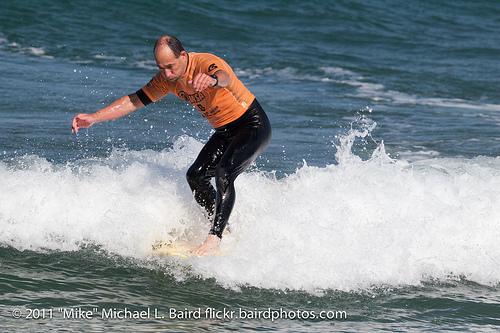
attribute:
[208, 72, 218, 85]
watch — black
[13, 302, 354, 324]
writing — on photo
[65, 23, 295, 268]
man — balding, surfing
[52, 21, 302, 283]
surfer — on board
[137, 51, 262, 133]
shirt — orange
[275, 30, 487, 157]
ocean — is wet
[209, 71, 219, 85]
wrist watch — on man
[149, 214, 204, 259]
surfboard — on man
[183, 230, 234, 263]
feet — are wet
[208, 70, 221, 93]
watch — on photo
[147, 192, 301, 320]
surfer — has brown hair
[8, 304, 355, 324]
writing — white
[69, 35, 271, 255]
man — wearing, balancing, holding, surfing, on board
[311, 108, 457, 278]
wave — small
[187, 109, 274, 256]
wetsuit — black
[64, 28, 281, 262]
man — standing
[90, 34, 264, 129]
shirt — orange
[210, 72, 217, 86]
wristwatch — black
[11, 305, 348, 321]
description — written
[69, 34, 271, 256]
surfer — is wet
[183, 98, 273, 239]
pants — black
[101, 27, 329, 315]
man — barefoot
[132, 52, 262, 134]
t shirt — on board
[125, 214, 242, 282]
surfboard — white